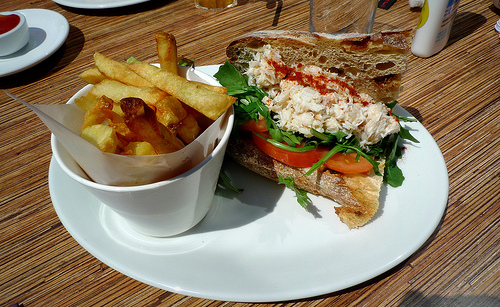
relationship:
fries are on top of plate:
[75, 32, 237, 155] [49, 63, 448, 302]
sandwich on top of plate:
[224, 29, 419, 227] [49, 63, 448, 302]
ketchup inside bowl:
[0, 16, 21, 35] [0, 13, 28, 56]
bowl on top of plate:
[0, 13, 28, 56] [0, 9, 69, 75]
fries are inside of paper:
[75, 32, 237, 155] [3, 73, 227, 186]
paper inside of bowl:
[3, 73, 227, 186] [50, 64, 234, 237]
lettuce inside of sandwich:
[214, 59, 418, 207] [224, 29, 419, 227]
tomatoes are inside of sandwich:
[240, 118, 373, 173] [224, 29, 419, 227]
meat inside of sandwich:
[243, 45, 399, 151] [224, 29, 419, 227]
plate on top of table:
[49, 63, 448, 302] [0, 0, 499, 305]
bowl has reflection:
[0, 13, 28, 56] [0, 28, 45, 60]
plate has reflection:
[0, 9, 69, 75] [1, 24, 84, 88]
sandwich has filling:
[224, 29, 419, 227] [214, 46, 418, 187]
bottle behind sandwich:
[309, 0, 379, 34] [224, 29, 419, 227]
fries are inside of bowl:
[75, 32, 237, 155] [50, 64, 234, 237]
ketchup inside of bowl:
[0, 16, 21, 35] [0, 13, 28, 56]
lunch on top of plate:
[75, 29, 419, 229] [49, 63, 448, 302]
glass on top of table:
[195, 0, 237, 10] [0, 0, 499, 305]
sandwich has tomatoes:
[224, 29, 419, 227] [240, 118, 373, 173]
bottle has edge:
[411, 0, 458, 58] [410, 48, 429, 59]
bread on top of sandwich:
[227, 28, 415, 102] [224, 29, 419, 227]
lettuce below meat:
[214, 59, 418, 207] [243, 45, 399, 151]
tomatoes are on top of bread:
[240, 118, 373, 173] [227, 135, 385, 229]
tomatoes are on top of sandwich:
[240, 118, 373, 173] [224, 29, 419, 227]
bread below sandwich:
[227, 135, 385, 229] [224, 29, 419, 227]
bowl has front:
[50, 64, 234, 237] [77, 155, 219, 237]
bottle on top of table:
[411, 0, 458, 58] [0, 0, 499, 305]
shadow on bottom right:
[398, 291, 499, 307] [395, 264, 498, 304]